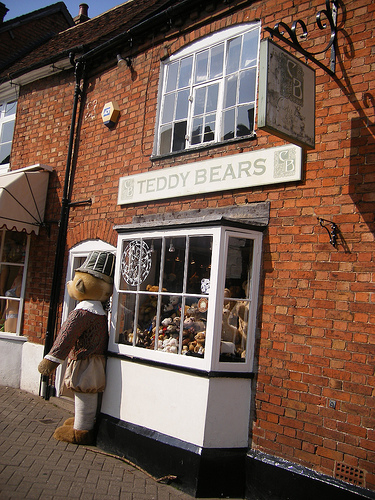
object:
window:
[151, 23, 261, 162]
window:
[1, 89, 21, 171]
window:
[105, 229, 261, 379]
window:
[2, 226, 32, 337]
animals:
[122, 279, 251, 361]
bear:
[39, 250, 117, 445]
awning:
[0, 165, 54, 238]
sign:
[255, 39, 315, 151]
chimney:
[72, 4, 93, 25]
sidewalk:
[2, 387, 204, 499]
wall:
[1, 1, 373, 492]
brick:
[287, 306, 315, 315]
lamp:
[113, 54, 132, 75]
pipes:
[39, 0, 197, 398]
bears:
[125, 284, 250, 361]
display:
[115, 237, 255, 376]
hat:
[69, 246, 114, 286]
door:
[56, 238, 116, 399]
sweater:
[41, 300, 114, 367]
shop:
[54, 150, 372, 492]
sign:
[117, 141, 304, 205]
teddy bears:
[134, 158, 266, 198]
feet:
[54, 417, 98, 447]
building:
[0, 2, 374, 500]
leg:
[65, 352, 105, 432]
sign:
[99, 104, 122, 128]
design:
[118, 240, 152, 284]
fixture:
[312, 217, 337, 251]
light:
[111, 52, 134, 74]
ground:
[2, 384, 197, 498]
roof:
[0, 1, 180, 89]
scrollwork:
[263, 2, 340, 81]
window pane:
[165, 60, 178, 92]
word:
[137, 158, 269, 198]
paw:
[37, 357, 59, 380]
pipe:
[39, 52, 86, 402]